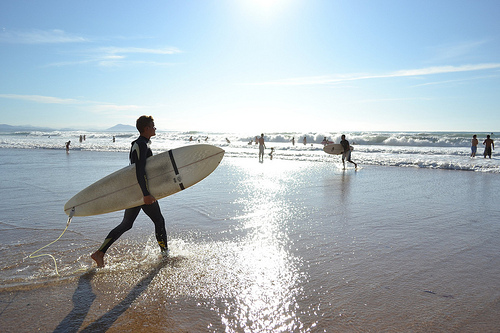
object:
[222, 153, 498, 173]
wave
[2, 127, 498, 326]
ocean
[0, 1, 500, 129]
sky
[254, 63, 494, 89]
clouds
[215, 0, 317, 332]
sun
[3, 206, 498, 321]
shore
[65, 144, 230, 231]
surfboard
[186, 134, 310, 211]
surf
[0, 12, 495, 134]
blue sky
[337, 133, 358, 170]
man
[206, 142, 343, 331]
light reflection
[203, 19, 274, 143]
sunshine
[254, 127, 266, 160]
man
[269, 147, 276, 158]
child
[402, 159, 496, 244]
beach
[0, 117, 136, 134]
mountains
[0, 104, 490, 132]
horizon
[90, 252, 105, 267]
foot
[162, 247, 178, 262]
foot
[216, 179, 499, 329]
water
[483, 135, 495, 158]
person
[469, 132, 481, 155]
person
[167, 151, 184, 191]
stripe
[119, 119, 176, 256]
man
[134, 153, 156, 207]
arm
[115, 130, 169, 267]
wetsuit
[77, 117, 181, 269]
man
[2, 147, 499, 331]
sand